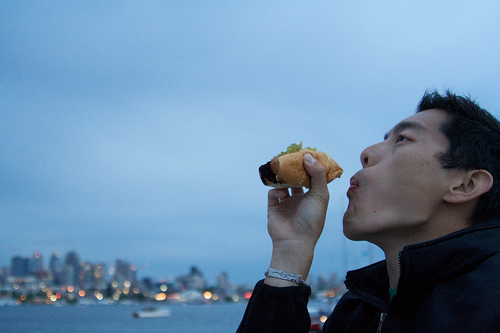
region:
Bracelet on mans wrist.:
[264, 268, 306, 284]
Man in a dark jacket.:
[233, 88, 498, 331]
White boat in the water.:
[133, 304, 170, 316]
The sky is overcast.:
[1, 3, 498, 248]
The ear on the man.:
[443, 168, 493, 200]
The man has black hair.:
[415, 87, 499, 224]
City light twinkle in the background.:
[0, 248, 252, 300]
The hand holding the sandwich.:
[267, 153, 327, 244]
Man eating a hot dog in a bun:
[227, 88, 495, 332]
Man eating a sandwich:
[230, 86, 498, 331]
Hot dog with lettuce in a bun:
[255, 137, 345, 191]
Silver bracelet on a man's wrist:
[260, 265, 309, 285]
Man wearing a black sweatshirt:
[230, 84, 499, 331]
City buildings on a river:
[0, 243, 345, 311]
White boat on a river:
[129, 297, 175, 321]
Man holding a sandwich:
[225, 83, 498, 330]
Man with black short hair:
[221, 86, 498, 331]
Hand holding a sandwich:
[252, 135, 344, 253]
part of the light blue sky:
[139, 161, 176, 215]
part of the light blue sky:
[36, 145, 94, 204]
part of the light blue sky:
[21, 75, 66, 118]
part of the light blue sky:
[103, 68, 148, 121]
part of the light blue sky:
[198, 80, 250, 140]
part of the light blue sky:
[314, 76, 368, 132]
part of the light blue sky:
[443, 24, 490, 89]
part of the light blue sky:
[338, 0, 391, 35]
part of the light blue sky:
[191, 0, 256, 23]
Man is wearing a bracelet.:
[263, 255, 308, 292]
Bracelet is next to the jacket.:
[251, 255, 316, 306]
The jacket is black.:
[342, 237, 499, 331]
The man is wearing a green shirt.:
[379, 274, 404, 310]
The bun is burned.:
[249, 146, 286, 189]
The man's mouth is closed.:
[340, 167, 370, 207]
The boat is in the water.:
[124, 300, 194, 323]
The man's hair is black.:
[422, 83, 498, 168]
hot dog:
[258, 130, 350, 205]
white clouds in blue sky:
[122, 126, 182, 176]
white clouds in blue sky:
[308, 5, 370, 60]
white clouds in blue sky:
[427, 18, 482, 66]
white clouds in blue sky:
[107, 59, 155, 126]